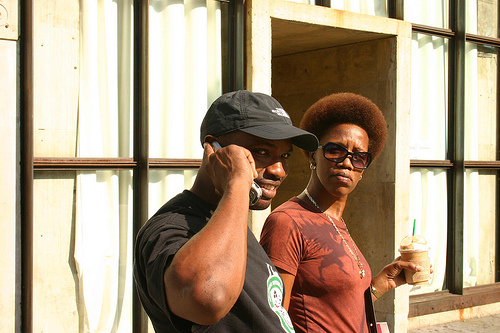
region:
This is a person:
[281, 78, 398, 307]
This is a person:
[135, 70, 300, 303]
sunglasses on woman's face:
[323, 137, 371, 172]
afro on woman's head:
[302, 89, 392, 152]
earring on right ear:
[304, 162, 320, 171]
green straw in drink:
[406, 220, 419, 247]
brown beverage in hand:
[395, 213, 435, 288]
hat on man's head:
[203, 89, 317, 149]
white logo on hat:
[265, 102, 293, 122]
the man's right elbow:
[182, 281, 237, 312]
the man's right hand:
[204, 146, 257, 187]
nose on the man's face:
[267, 158, 285, 182]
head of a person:
[299, 86, 391, 200]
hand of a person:
[190, 126, 268, 190]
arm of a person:
[199, 178, 261, 318]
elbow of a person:
[173, 271, 224, 321]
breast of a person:
[309, 235, 391, 300]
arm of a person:
[255, 246, 307, 321]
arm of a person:
[355, 248, 423, 323]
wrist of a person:
[372, 251, 409, 299]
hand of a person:
[399, 239, 447, 301]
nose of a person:
[333, 155, 368, 172]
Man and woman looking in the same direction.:
[130, 82, 433, 329]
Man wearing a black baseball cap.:
[128, 89, 319, 331]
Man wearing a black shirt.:
[129, 85, 320, 332]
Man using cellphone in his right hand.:
[134, 79, 321, 331]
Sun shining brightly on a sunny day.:
[2, 1, 495, 328]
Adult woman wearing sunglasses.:
[260, 93, 433, 332]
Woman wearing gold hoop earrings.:
[257, 91, 430, 331]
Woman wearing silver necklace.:
[256, 90, 429, 331]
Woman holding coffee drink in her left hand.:
[260, 89, 429, 331]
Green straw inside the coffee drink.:
[393, 215, 436, 292]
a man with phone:
[185, 80, 310, 232]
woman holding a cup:
[297, 97, 447, 317]